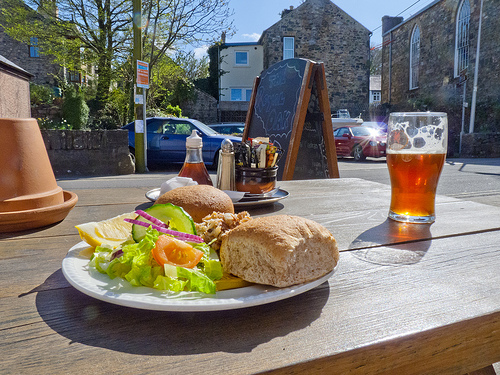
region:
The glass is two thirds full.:
[376, 98, 457, 235]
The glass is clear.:
[373, 98, 458, 234]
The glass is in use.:
[374, 103, 453, 233]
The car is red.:
[330, 110, 398, 164]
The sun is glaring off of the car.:
[328, 110, 393, 164]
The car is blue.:
[116, 93, 251, 175]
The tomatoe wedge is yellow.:
[141, 232, 210, 277]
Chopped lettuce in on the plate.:
[62, 180, 345, 314]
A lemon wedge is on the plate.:
[56, 178, 350, 316]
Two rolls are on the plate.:
[55, 175, 351, 322]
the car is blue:
[126, 101, 246, 162]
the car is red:
[326, 93, 388, 160]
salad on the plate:
[114, 197, 214, 302]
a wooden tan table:
[307, 167, 444, 367]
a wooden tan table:
[46, 165, 166, 312]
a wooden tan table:
[218, 116, 405, 366]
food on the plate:
[62, 161, 336, 348]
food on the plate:
[44, 132, 265, 292]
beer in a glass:
[334, 87, 461, 294]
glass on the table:
[361, 95, 467, 223]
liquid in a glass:
[377, 140, 445, 217]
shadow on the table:
[350, 221, 439, 274]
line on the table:
[343, 221, 394, 279]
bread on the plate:
[218, 200, 334, 298]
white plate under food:
[132, 290, 171, 314]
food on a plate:
[106, 171, 302, 291]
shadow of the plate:
[23, 306, 92, 355]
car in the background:
[111, 106, 238, 172]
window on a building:
[226, 45, 256, 75]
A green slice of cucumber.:
[132, 203, 197, 243]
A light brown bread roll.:
[219, 215, 338, 287]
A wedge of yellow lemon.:
[76, 210, 141, 246]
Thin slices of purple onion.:
[127, 210, 202, 250]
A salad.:
[93, 205, 221, 300]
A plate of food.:
[57, 179, 342, 319]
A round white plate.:
[62, 218, 342, 313]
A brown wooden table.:
[0, 179, 497, 373]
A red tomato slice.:
[151, 235, 202, 269]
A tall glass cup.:
[385, 108, 448, 225]